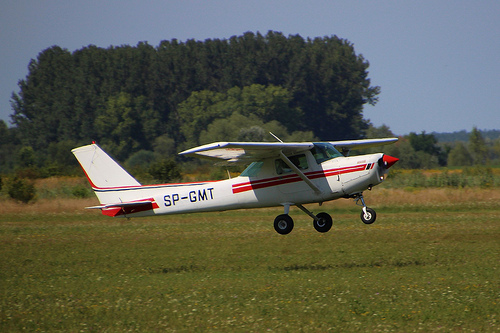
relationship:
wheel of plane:
[271, 214, 297, 243] [76, 130, 390, 247]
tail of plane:
[76, 121, 148, 200] [76, 130, 390, 247]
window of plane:
[268, 148, 319, 186] [76, 130, 390, 247]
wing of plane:
[103, 194, 170, 244] [76, 130, 390, 247]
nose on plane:
[378, 149, 413, 176] [76, 130, 390, 247]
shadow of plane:
[266, 247, 438, 286] [76, 130, 390, 247]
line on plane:
[230, 159, 376, 196] [76, 130, 390, 247]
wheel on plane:
[271, 214, 297, 243] [76, 130, 390, 247]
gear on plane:
[269, 214, 341, 244] [76, 130, 390, 247]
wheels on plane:
[270, 192, 390, 249] [76, 130, 390, 247]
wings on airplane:
[189, 129, 394, 168] [76, 105, 391, 240]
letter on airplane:
[161, 186, 214, 209] [76, 105, 391, 240]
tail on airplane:
[76, 121, 148, 200] [76, 105, 391, 240]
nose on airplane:
[378, 149, 413, 176] [76, 105, 391, 240]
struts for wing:
[279, 156, 329, 197] [189, 114, 356, 188]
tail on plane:
[76, 121, 148, 200] [76, 130, 390, 247]